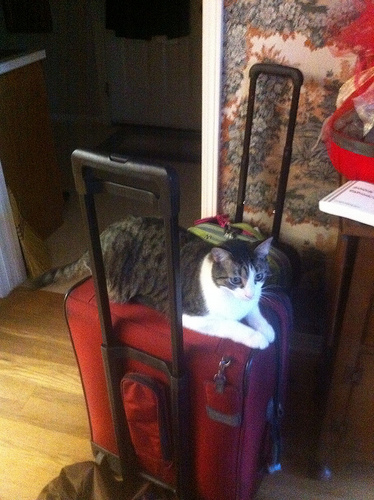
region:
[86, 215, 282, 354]
Tabby cat contently sitting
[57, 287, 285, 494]
A red suitcase under the cat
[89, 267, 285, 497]
Cat lying on a red pull along suitcase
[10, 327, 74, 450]
Wood floor is light in color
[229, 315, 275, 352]
Two white paws of cat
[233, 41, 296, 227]
Black handle of a pull along suitcase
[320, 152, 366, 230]
Book sitting on the counter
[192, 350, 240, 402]
Zipper of suitcase is closed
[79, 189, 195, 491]
Black handle on suitcase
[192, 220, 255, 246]
Light green suitcase behind cat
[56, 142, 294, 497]
a suitcase on the ground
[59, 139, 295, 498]
the suitcase is red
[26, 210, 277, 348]
the cat is sitting on the suitcase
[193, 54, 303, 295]
another suitcase behind the cat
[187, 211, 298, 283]
this suitcase is green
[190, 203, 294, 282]
a pink tag on the green suitcase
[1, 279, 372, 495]
the floor is wooden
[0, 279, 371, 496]
the floorboards are brown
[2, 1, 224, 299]
the door frame is white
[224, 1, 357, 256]
blue flowers on the wallpaper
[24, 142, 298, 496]
a cat is ready for a trip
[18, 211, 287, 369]
the kitty is lying on a red suitcase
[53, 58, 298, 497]
two suitcases are near the door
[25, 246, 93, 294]
the cat's tail is striped black and gray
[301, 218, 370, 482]
a wooden cabinet is in the room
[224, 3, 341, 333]
a floral wallpaper is on the wall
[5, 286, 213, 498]
the floor is wooden under the cases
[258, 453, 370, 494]
the floor is carpeted under the cases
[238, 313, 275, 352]
the cat has white paws on the luggage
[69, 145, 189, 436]
a black telescoping handle is on the case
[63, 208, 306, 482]
cat laying across upright suitcase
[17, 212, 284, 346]
dark cat with large white markings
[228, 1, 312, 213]
patterned wallpaper of flowers and shrubs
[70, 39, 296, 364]
black handles extended on suitcases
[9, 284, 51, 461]
brown wooden floor of narrow strips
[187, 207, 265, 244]
red tag through handle of green suitcase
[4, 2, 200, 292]
doorway into dark room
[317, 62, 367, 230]
book, plastic bag and red bowl on table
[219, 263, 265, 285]
watchful almond-shaped eyes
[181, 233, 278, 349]
white front paws, bib and lower face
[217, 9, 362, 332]
Gray and white design on wall.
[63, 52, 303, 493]
Two suitcases indicating someone going on a trip.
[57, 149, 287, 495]
Red pull along suitcase with gray and black trim.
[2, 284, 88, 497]
Wooden floor with different browns.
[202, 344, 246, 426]
Identification tag with silver attachment.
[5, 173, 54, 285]
Straw broom with thread binding.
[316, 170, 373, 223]
Gray and white book on table.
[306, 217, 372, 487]
Corner of wooden antique table.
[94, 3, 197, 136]
Closed white wooden door.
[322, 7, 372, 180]
Red bowl with red and white bow.